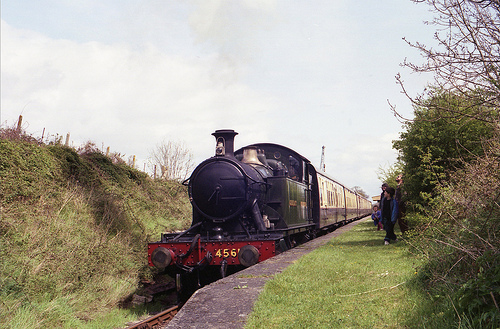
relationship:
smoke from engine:
[184, 0, 280, 129] [145, 129, 311, 267]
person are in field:
[383, 187, 399, 246] [254, 206, 423, 324]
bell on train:
[214, 135, 228, 156] [146, 129, 372, 265]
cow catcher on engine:
[146, 236, 285, 265] [145, 129, 311, 267]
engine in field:
[145, 129, 311, 267] [254, 206, 423, 324]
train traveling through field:
[146, 129, 372, 265] [254, 206, 423, 324]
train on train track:
[146, 129, 372, 265] [123, 303, 183, 328]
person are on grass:
[383, 187, 399, 246] [1, 206, 449, 328]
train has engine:
[146, 129, 372, 265] [145, 129, 311, 267]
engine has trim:
[145, 129, 311, 267] [146, 236, 285, 265]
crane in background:
[319, 145, 330, 177] [2, 2, 396, 173]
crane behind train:
[319, 145, 330, 177] [146, 129, 372, 265]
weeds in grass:
[20, 179, 143, 268] [1, 206, 449, 328]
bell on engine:
[214, 135, 228, 156] [145, 129, 311, 267]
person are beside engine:
[383, 187, 399, 246] [145, 129, 311, 267]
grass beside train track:
[1, 206, 449, 328] [123, 303, 183, 328]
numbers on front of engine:
[215, 248, 246, 258] [145, 129, 311, 267]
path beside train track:
[166, 214, 376, 328] [123, 303, 183, 328]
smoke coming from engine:
[184, 0, 280, 129] [145, 129, 311, 267]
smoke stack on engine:
[212, 129, 238, 156] [145, 129, 311, 267]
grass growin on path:
[1, 206, 449, 328] [166, 214, 376, 328]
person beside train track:
[383, 187, 399, 246] [123, 303, 183, 328]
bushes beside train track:
[392, 94, 498, 324] [123, 303, 183, 328]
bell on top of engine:
[214, 135, 228, 156] [145, 129, 311, 267]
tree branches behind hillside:
[147, 141, 197, 184] [1, 135, 192, 318]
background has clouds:
[2, 2, 396, 173] [4, 23, 185, 140]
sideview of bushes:
[387, 1, 499, 328] [392, 94, 498, 324]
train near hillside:
[146, 129, 372, 265] [1, 135, 192, 318]